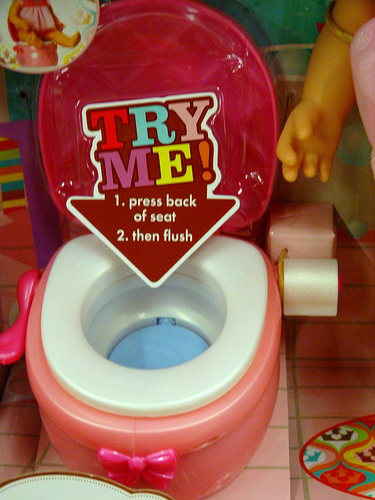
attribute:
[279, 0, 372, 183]
doll arm — Doll 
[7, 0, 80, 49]
bear picture — Bear 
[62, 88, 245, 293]
sign — Try me 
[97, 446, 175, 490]
bow — Pink 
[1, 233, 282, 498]
toilet bowl — toilet  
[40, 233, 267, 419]
bowl — toilet 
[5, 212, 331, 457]
toilet — Plastic paper toilet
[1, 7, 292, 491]
bowl — Toy toilet 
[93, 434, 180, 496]
bow — Pink 